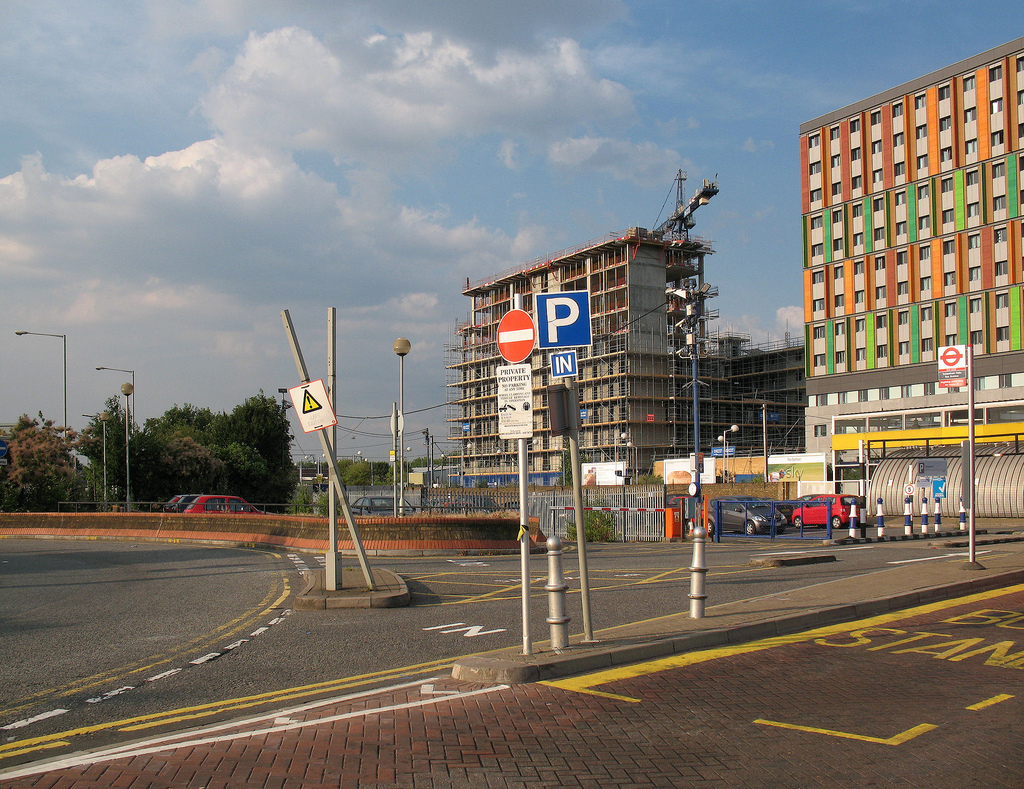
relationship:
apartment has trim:
[795, 30, 1023, 452] [876, 93, 902, 193]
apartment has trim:
[795, 30, 1023, 452] [967, 66, 996, 168]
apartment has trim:
[795, 30, 1023, 452] [836, 114, 856, 205]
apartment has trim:
[795, 30, 1023, 452] [900, 187, 920, 250]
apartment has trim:
[795, 30, 1023, 452] [950, 168, 966, 240]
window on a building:
[809, 320, 829, 344] [789, 41, 1023, 479]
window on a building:
[846, 317, 870, 330] [789, 41, 1023, 479]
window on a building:
[852, 343, 869, 359] [789, 41, 1023, 479]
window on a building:
[831, 348, 848, 365] [789, 41, 1023, 479]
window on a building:
[812, 354, 831, 370] [789, 41, 1023, 479]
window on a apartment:
[830, 291, 853, 308] [796, 36, 1024, 452]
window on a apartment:
[877, 120, 904, 150] [796, 36, 1024, 452]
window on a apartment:
[883, 336, 904, 359] [796, 36, 1024, 452]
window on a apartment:
[987, 320, 1010, 340] [796, 36, 1024, 452]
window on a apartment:
[949, 101, 987, 131] [796, 36, 1024, 452]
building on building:
[445, 223, 805, 519] [821, 112, 940, 327]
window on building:
[955, 68, 979, 91] [780, 45, 1022, 532]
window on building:
[958, 200, 981, 224] [780, 45, 1022, 532]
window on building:
[867, 222, 887, 242] [780, 45, 1022, 532]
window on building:
[967, 298, 984, 317] [780, 45, 1022, 532]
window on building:
[809, 346, 838, 373] [780, 45, 1022, 532]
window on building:
[872, 313, 885, 326] [789, 41, 1023, 479]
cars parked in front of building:
[720, 465, 863, 530] [789, 41, 1023, 479]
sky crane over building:
[680, 181, 719, 245] [445, 223, 805, 519]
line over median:
[714, 496, 976, 545] [436, 528, 1013, 696]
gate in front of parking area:
[711, 491, 845, 542] [677, 441, 978, 544]